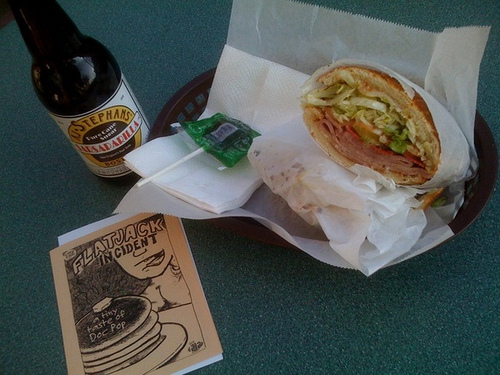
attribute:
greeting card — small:
[49, 213, 223, 373]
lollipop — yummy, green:
[135, 111, 262, 190]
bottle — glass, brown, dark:
[10, 1, 152, 186]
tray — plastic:
[148, 69, 498, 248]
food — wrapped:
[299, 63, 442, 181]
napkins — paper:
[124, 122, 273, 214]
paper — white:
[249, 134, 426, 252]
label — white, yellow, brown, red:
[49, 71, 149, 181]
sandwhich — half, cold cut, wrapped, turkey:
[302, 61, 441, 186]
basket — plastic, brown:
[142, 64, 499, 249]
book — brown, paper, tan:
[48, 212, 222, 373]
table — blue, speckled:
[2, 4, 499, 374]